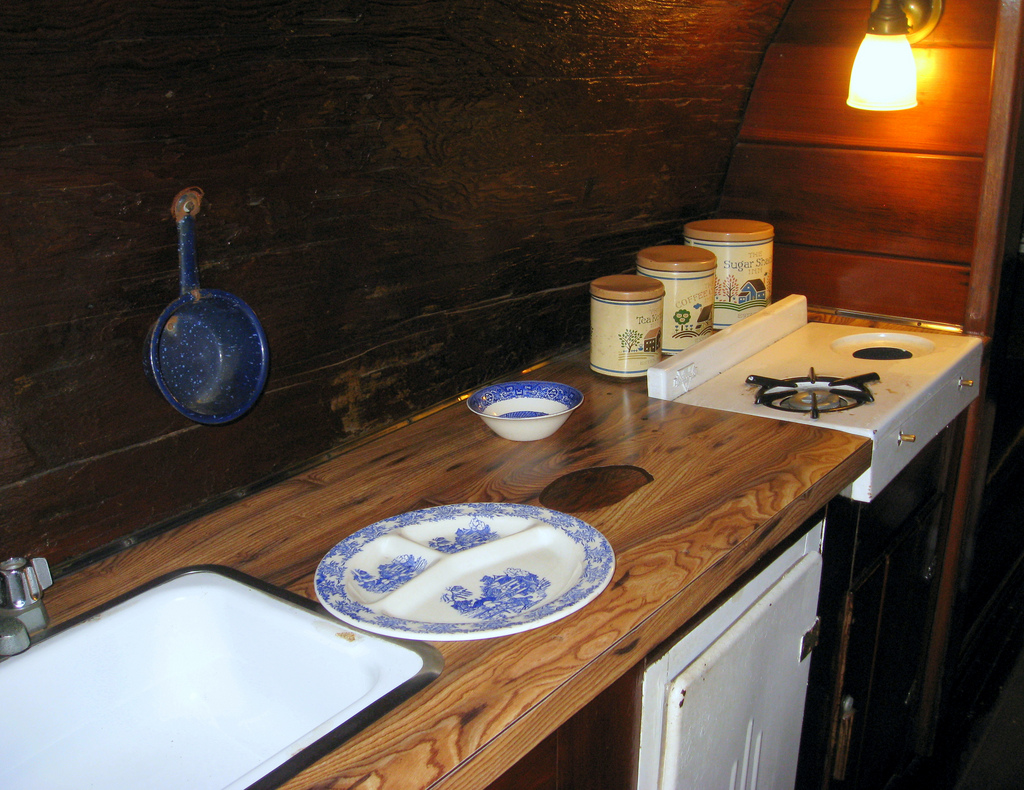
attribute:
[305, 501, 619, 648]
plate — blue, white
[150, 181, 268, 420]
pot — blue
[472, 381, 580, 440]
bowl — blue, white, empty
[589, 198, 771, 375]
canisters — three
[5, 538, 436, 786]
sink — silver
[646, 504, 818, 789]
refrigerator — small and white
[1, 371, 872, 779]
counter — wooden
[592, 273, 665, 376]
canister — cream, tan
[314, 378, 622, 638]
dishes — blue and white 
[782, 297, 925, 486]
stove top — small and white